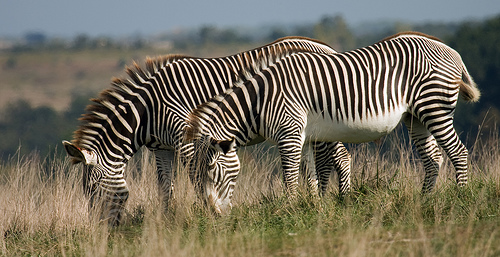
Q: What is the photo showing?
A: It is showing a field.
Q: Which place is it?
A: It is a field.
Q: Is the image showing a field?
A: Yes, it is showing a field.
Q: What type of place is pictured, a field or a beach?
A: It is a field.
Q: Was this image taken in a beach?
A: No, the picture was taken in a field.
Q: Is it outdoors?
A: Yes, it is outdoors.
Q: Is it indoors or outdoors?
A: It is outdoors.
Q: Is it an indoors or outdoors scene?
A: It is outdoors.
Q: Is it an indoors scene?
A: No, it is outdoors.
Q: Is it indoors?
A: No, it is outdoors.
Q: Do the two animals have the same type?
A: Yes, all the animals are zebras.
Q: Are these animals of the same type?
A: Yes, all the animals are zebras.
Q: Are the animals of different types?
A: No, all the animals are zebras.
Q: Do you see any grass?
A: Yes, there is grass.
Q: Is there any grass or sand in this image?
A: Yes, there is grass.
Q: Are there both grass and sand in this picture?
A: No, there is grass but no sand.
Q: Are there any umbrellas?
A: No, there are no umbrellas.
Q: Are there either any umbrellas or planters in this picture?
A: No, there are no umbrellas or planters.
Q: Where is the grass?
A: The grass is in the field.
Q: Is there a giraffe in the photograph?
A: No, there are no giraffes.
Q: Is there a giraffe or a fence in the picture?
A: No, there are no giraffes or fences.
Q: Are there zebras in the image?
A: Yes, there is a zebra.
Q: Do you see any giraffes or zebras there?
A: Yes, there is a zebra.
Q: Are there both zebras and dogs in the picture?
A: No, there is a zebra but no dogs.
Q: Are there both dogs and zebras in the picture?
A: No, there is a zebra but no dogs.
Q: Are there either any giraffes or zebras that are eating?
A: Yes, the zebra is eating.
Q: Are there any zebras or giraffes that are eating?
A: Yes, the zebra is eating.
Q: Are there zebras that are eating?
A: Yes, there is a zebra that is eating.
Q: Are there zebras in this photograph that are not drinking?
A: Yes, there is a zebra that is eating.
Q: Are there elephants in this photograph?
A: No, there are no elephants.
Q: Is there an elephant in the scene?
A: No, there are no elephants.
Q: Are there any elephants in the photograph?
A: No, there are no elephants.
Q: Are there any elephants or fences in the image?
A: No, there are no elephants or fences.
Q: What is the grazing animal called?
A: The animal is a zebra.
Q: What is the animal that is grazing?
A: The animal is a zebra.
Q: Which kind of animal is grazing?
A: The animal is a zebra.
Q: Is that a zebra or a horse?
A: That is a zebra.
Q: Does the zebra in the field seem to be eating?
A: Yes, the zebra is eating.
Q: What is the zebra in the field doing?
A: The zebra is eating.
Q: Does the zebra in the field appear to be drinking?
A: No, the zebra is eating.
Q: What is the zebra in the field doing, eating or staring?
A: The zebra is eating.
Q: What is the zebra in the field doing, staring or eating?
A: The zebra is eating.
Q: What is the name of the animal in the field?
A: The animal is a zebra.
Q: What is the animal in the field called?
A: The animal is a zebra.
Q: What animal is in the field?
A: The animal is a zebra.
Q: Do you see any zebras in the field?
A: Yes, there is a zebra in the field.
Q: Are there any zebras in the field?
A: Yes, there is a zebra in the field.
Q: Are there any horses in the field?
A: No, there is a zebra in the field.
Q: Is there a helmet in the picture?
A: No, there are no helmets.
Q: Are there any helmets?
A: No, there are no helmets.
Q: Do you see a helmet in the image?
A: No, there are no helmets.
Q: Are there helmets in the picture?
A: No, there are no helmets.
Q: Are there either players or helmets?
A: No, there are no helmets or players.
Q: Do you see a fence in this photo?
A: No, there are no fences.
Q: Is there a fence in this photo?
A: No, there are no fences.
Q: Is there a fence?
A: No, there are no fences.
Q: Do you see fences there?
A: No, there are no fences.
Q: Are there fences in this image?
A: No, there are no fences.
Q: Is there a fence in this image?
A: No, there are no fences.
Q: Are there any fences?
A: No, there are no fences.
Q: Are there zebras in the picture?
A: Yes, there is a zebra.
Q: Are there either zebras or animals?
A: Yes, there is a zebra.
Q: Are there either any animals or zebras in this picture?
A: Yes, there is a zebra.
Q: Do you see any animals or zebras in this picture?
A: Yes, there is a zebra.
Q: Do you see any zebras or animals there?
A: Yes, there is a zebra.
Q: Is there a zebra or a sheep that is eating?
A: Yes, the zebra is eating.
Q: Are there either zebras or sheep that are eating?
A: Yes, the zebra is eating.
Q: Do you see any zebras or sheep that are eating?
A: Yes, the zebra is eating.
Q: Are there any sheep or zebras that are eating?
A: Yes, the zebra is eating.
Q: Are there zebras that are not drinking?
A: Yes, there is a zebra that is eating.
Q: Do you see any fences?
A: No, there are no fences.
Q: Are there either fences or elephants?
A: No, there are no fences or elephants.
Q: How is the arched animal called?
A: The animal is a zebra.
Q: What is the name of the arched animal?
A: The animal is a zebra.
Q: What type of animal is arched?
A: The animal is a zebra.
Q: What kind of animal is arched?
A: The animal is a zebra.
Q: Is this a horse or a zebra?
A: This is a zebra.